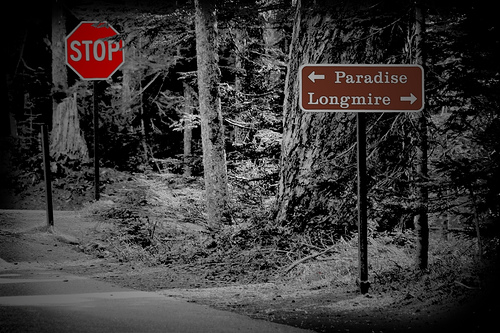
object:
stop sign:
[60, 20, 127, 83]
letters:
[68, 38, 127, 63]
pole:
[89, 80, 105, 206]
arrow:
[301, 69, 337, 88]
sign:
[296, 62, 424, 116]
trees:
[187, 4, 235, 252]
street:
[2, 199, 290, 332]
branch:
[160, 89, 205, 127]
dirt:
[122, 272, 175, 326]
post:
[352, 114, 375, 269]